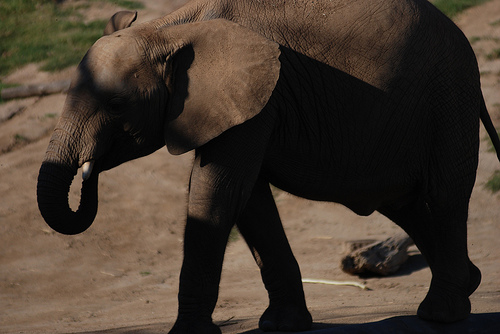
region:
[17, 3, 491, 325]
Close up of an elephant.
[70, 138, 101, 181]
Tusk on left side of elephant.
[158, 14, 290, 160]
Ear on left side of elephant.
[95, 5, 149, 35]
Top of elephant's right ear.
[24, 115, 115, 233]
Trunk of elephant is curled up to mouth.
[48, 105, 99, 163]
Wrinkled skin on elephant's trunk.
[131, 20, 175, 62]
Wrinkled skin on elephant's head.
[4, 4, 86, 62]
A section of green grass.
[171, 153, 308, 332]
Elephan'ts front legs.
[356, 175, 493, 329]
Elephant's back legs.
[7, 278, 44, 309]
brown dirt on ground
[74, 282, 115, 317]
brown dirt on ground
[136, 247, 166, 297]
brown dirt on ground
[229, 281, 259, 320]
brown dirt on ground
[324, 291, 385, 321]
brown dirt on ground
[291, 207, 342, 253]
brown dirt on ground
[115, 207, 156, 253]
brown dirt on ground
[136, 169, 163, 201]
brown dirt on ground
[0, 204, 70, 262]
brown dirt on ground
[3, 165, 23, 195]
brown dirt on ground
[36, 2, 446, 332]
The elephant plods slowly along in the dirt.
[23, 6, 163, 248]
Elephant eating something.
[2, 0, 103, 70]
Grass grows in the area.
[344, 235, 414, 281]
A single rock litters the ground.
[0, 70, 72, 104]
A tree has fallen and left behind the trunk.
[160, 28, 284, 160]
The elephant has large ears.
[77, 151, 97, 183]
The tusks of the elephant are small.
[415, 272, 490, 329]
The elephant has large feet.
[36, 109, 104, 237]
The elephant has a long trunk.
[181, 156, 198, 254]
The elephant has hair covering its body.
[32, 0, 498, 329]
an elephant in a zoo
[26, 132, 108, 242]
the trunk of an elephant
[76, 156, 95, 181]
the tusk of an elephant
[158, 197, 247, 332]
the leg of an elephant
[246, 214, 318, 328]
the leg of an elephant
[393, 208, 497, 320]
the rear legs of an elephant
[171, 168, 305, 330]
the front legs of an elephant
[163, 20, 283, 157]
the ear of an elephant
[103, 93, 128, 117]
the eye of an elephant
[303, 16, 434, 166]
the skin of an elephant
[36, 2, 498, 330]
Elephant walking alone on the sand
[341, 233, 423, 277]
Driftwood sitting on top of the sand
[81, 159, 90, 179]
Tusk sticking out of elephan'ts mouth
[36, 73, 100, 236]
Elephant's trunk inside of its mouth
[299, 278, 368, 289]
Dry stick lying on the ground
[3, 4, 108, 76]
Green grass in the background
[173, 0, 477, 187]
Wrinkles on side of elephant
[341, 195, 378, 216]
Protrusion on bottom of elephant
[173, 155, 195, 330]
Stubble on side of elephant's leg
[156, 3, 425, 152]
Sun shining on back and side of elephant